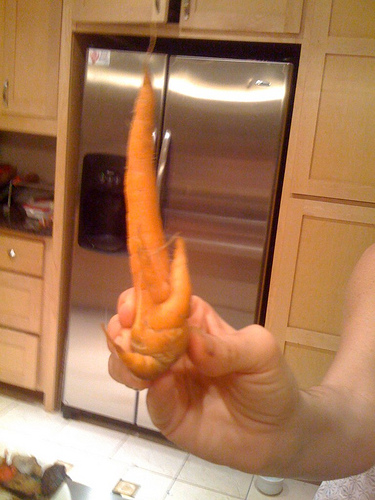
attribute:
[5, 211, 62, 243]
countertop — granite , kitchen countertop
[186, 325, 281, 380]
thumb — crooked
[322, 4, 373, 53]
wooden cabinet — several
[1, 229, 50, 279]
kitchen drawer — light brown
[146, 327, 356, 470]
elbow — bend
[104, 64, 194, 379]
carrot — odd shaped 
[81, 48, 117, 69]
tag — white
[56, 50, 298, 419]
refrigerator — large, stainless steel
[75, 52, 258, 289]
fridge — silver, stainless steel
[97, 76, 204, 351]
carrot — strange orange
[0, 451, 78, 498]
grout — dark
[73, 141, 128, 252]
water dispenser — black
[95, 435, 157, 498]
tile — kitchen floor tile